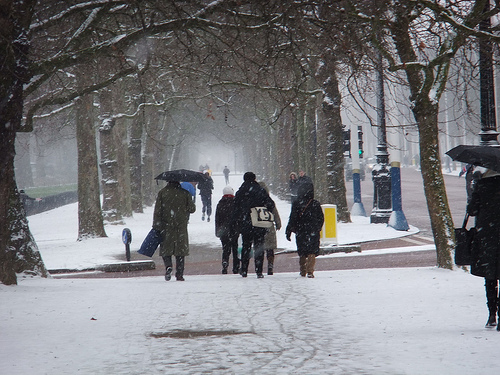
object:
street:
[347, 160, 476, 265]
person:
[464, 144, 500, 331]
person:
[230, 171, 276, 277]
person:
[214, 186, 243, 274]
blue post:
[386, 166, 409, 231]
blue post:
[350, 172, 367, 216]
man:
[152, 177, 196, 280]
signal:
[357, 147, 364, 156]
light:
[357, 126, 363, 159]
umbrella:
[153, 168, 212, 185]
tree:
[2, 0, 149, 284]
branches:
[26, 12, 369, 131]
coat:
[152, 180, 196, 256]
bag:
[249, 205, 277, 230]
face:
[257, 206, 271, 221]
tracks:
[144, 275, 364, 374]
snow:
[0, 171, 498, 373]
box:
[316, 204, 337, 246]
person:
[197, 171, 215, 223]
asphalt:
[347, 166, 470, 236]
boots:
[309, 256, 315, 276]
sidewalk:
[1, 265, 499, 375]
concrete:
[343, 235, 443, 269]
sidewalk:
[46, 233, 435, 278]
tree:
[388, 1, 498, 271]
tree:
[15, 1, 152, 242]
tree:
[284, 3, 400, 222]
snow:
[29, 31, 495, 113]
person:
[283, 182, 326, 277]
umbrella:
[444, 144, 500, 172]